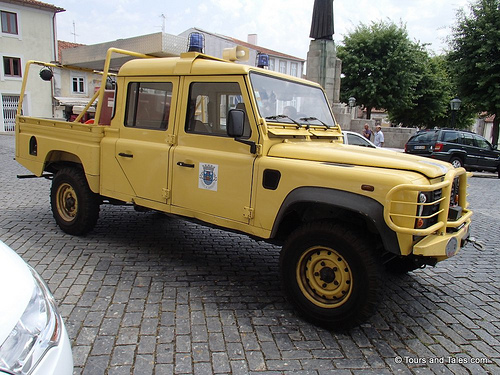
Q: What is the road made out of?
A: Bricks.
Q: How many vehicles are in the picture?
A: Three.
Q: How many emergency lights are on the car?
A: Two.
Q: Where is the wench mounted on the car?
A: The front.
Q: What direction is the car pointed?
A: Right.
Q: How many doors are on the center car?
A: Four.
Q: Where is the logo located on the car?
A: On the door.